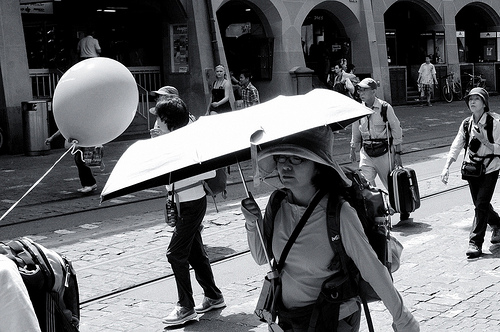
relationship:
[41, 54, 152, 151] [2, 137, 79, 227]
balloon on string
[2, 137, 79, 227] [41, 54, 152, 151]
string on balloon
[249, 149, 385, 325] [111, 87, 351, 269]
lady has umbrella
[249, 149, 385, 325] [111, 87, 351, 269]
lady holding umbrella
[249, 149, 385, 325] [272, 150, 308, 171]
lady has glasses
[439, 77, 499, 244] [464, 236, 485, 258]
woman has shoe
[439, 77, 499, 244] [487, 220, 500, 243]
woman wearing shoe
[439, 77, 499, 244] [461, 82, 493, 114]
woman has hat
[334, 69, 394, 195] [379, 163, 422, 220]
man has suitcase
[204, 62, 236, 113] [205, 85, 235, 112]
girl has dress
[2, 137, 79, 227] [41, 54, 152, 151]
string attached balloon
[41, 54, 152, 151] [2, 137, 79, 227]
balloon float string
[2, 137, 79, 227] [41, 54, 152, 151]
string tied balloon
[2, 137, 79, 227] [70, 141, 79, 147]
string has knot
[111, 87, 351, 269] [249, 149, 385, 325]
umbrella over lady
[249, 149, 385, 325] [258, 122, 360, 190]
lady wearing hat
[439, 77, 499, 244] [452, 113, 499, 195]
woman wearing shirt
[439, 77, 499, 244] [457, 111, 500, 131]
woman has backpack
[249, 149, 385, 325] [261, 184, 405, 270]
lady has backpack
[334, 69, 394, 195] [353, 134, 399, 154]
man has bellypack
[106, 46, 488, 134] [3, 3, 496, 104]
people near building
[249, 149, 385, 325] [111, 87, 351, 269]
person holding umbrella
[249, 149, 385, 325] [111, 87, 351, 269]
person under umbrella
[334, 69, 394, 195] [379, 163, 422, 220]
person carrying suitcase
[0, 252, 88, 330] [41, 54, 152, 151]
person holding balloon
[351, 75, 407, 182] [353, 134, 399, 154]
person has fannypack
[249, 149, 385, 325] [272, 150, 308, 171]
woman has glasses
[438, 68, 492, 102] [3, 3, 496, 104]
bikes outside building